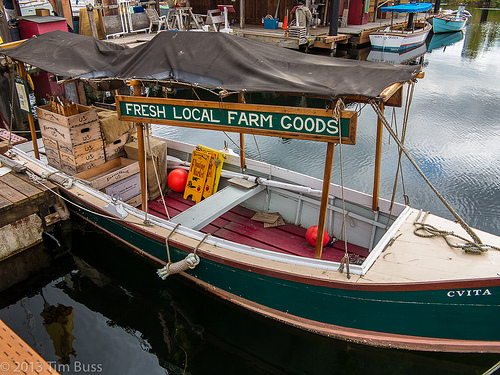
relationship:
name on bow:
[442, 280, 492, 307] [478, 251, 495, 353]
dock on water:
[8, 183, 59, 223] [418, 109, 457, 131]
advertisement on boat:
[118, 91, 354, 146] [220, 54, 319, 302]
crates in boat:
[57, 122, 105, 147] [220, 54, 319, 302]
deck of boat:
[241, 226, 250, 230] [220, 54, 319, 302]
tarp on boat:
[276, 74, 293, 83] [220, 54, 319, 302]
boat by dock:
[220, 54, 319, 302] [8, 183, 59, 223]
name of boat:
[442, 280, 492, 307] [220, 54, 319, 302]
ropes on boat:
[84, 212, 146, 228] [220, 54, 319, 302]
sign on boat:
[312, 111, 332, 135] [220, 54, 319, 302]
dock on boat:
[8, 183, 59, 223] [220, 54, 319, 302]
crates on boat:
[57, 122, 105, 147] [220, 54, 319, 302]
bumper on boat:
[172, 173, 193, 181] [220, 54, 319, 302]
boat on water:
[220, 54, 319, 302] [418, 109, 457, 131]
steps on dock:
[48, 206, 68, 218] [8, 183, 59, 223]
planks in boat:
[107, 172, 140, 194] [220, 54, 319, 302]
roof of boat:
[179, 83, 200, 93] [220, 54, 319, 302]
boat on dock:
[220, 54, 319, 302] [8, 183, 59, 223]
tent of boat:
[163, 28, 213, 47] [220, 54, 319, 302]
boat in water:
[220, 54, 319, 302] [418, 109, 457, 131]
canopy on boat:
[71, 57, 113, 84] [220, 54, 319, 302]